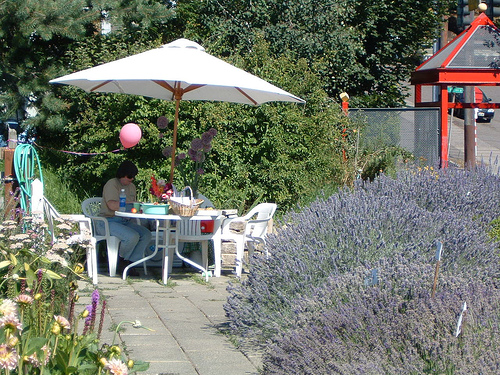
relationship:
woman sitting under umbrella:
[93, 160, 153, 276] [28, 4, 313, 160]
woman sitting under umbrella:
[93, 160, 153, 276] [36, 13, 336, 178]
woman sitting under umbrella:
[93, 160, 153, 276] [38, 24, 312, 160]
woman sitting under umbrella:
[93, 160, 153, 276] [23, 19, 310, 155]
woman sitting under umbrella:
[93, 160, 153, 276] [39, 17, 306, 138]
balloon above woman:
[119, 123, 141, 149] [88, 151, 151, 220]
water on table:
[108, 182, 137, 222] [92, 195, 235, 235]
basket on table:
[169, 186, 204, 217] [103, 204, 235, 296]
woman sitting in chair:
[93, 160, 153, 276] [42, 164, 137, 280]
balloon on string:
[119, 123, 141, 149] [86, 136, 121, 226]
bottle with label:
[119, 189, 127, 212] [118, 174, 138, 202]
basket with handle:
[165, 180, 207, 228] [168, 186, 218, 224]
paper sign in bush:
[425, 215, 458, 300] [221, 130, 500, 375]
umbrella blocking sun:
[45, 19, 305, 123] [205, 19, 300, 66]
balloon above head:
[119, 123, 141, 149] [99, 166, 129, 207]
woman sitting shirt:
[93, 160, 153, 276] [98, 177, 138, 213]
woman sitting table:
[93, 160, 153, 276] [102, 190, 258, 279]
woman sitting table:
[91, 166, 162, 279] [90, 190, 252, 294]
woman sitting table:
[93, 160, 153, 276] [104, 189, 240, 295]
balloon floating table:
[118, 120, 149, 151] [103, 170, 240, 279]